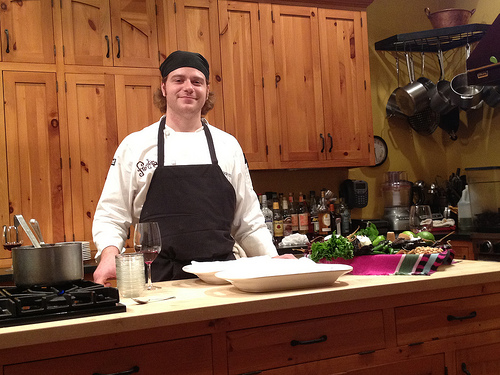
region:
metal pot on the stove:
[7, 240, 90, 287]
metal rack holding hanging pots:
[374, 19, 494, 55]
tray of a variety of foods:
[311, 234, 457, 272]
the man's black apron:
[139, 114, 241, 285]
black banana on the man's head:
[154, 47, 214, 84]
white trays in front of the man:
[182, 254, 354, 296]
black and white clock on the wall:
[366, 134, 389, 169]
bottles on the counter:
[261, 189, 350, 241]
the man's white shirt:
[86, 114, 281, 272]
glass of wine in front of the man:
[126, 219, 165, 293]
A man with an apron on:
[85, 48, 294, 285]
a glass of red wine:
[120, 214, 170, 289]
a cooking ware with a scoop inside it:
[8, 211, 91, 291]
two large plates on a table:
[177, 237, 352, 294]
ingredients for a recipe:
[308, 216, 459, 276]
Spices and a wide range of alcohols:
[256, 180, 361, 242]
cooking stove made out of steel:
[2, 277, 129, 322]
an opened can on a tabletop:
[115, 247, 149, 302]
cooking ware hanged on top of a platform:
[373, 19, 493, 124]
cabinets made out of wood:
[7, 2, 376, 174]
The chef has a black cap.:
[156, 51, 219, 68]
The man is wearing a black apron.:
[148, 136, 238, 265]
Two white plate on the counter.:
[198, 245, 340, 303]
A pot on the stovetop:
[6, 203, 116, 306]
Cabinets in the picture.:
[231, 14, 398, 174]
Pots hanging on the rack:
[389, 46, 474, 132]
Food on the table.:
[310, 220, 408, 248]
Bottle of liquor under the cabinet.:
[260, 198, 339, 231]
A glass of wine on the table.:
[126, 218, 171, 288]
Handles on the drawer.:
[285, 330, 341, 352]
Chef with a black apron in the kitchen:
[90, 48, 302, 293]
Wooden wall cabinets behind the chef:
[0, 0, 378, 283]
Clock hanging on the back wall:
[368, 133, 391, 172]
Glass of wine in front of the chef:
[129, 218, 164, 297]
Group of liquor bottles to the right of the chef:
[255, 186, 360, 246]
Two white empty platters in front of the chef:
[180, 248, 356, 295]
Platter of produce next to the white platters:
[304, 219, 460, 274]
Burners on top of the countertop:
[0, 275, 128, 333]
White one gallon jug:
[453, 181, 475, 221]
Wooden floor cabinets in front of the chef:
[0, 278, 499, 373]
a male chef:
[91, 50, 293, 285]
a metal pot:
[11, 219, 83, 286]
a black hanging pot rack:
[375, 21, 494, 133]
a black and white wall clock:
[367, 133, 387, 167]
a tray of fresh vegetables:
[310, 222, 452, 274]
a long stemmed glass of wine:
[131, 221, 162, 291]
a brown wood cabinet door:
[319, 7, 373, 165]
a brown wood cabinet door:
[270, 1, 326, 165]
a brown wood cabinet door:
[218, 0, 265, 165]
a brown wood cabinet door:
[110, 0, 164, 70]